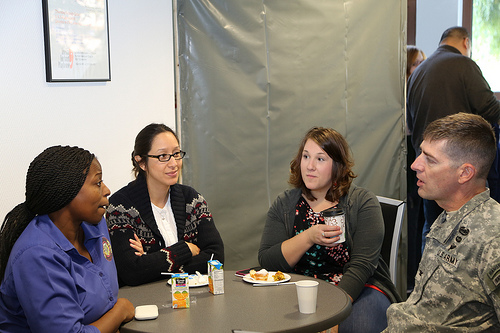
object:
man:
[379, 111, 500, 332]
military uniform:
[379, 186, 500, 332]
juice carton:
[171, 272, 190, 308]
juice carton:
[207, 260, 224, 295]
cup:
[295, 280, 319, 314]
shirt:
[0, 214, 118, 333]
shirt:
[294, 194, 353, 286]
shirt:
[150, 193, 178, 248]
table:
[116, 270, 352, 333]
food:
[249, 269, 286, 282]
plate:
[243, 271, 292, 284]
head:
[411, 112, 498, 200]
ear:
[458, 163, 475, 184]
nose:
[411, 154, 425, 171]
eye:
[427, 158, 435, 164]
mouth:
[416, 176, 424, 186]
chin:
[418, 187, 436, 200]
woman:
[257, 125, 402, 332]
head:
[300, 127, 347, 189]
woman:
[105, 122, 224, 288]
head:
[134, 123, 182, 185]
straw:
[160, 272, 175, 276]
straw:
[210, 253, 214, 261]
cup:
[323, 209, 346, 243]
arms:
[106, 200, 182, 286]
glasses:
[148, 150, 186, 162]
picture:
[47, 0, 110, 80]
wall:
[2, 1, 175, 221]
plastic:
[173, 1, 409, 298]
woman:
[0, 144, 135, 332]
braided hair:
[0, 144, 94, 272]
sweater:
[106, 171, 225, 287]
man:
[406, 26, 500, 257]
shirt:
[407, 44, 500, 157]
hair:
[288, 126, 358, 202]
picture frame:
[40, 0, 110, 83]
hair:
[424, 113, 496, 180]